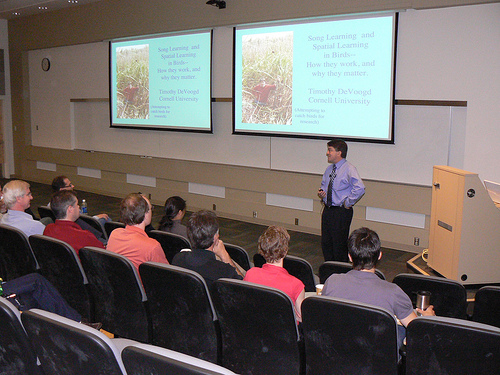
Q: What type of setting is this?
A: Classroom.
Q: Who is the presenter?
A: Timothy DeVoogd.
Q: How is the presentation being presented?
A: Via powerpoint.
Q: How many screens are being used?
A: 2.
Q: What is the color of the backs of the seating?
A: Black.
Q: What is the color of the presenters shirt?
A: Purple.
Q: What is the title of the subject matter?
A: Song Learning and Spatial Learning in Birds. How They Work and Why They Matter.